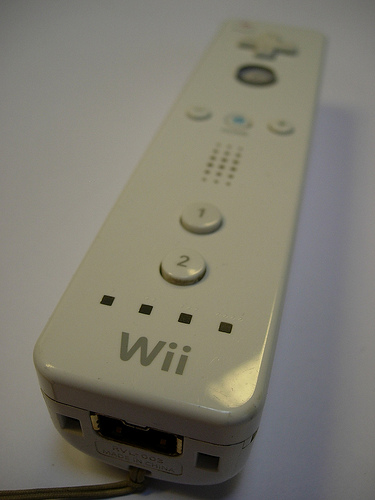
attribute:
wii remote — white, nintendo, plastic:
[16, 14, 341, 483]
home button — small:
[237, 63, 272, 92]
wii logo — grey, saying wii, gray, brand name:
[111, 328, 196, 377]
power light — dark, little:
[137, 302, 156, 317]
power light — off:
[178, 311, 195, 326]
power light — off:
[216, 318, 236, 336]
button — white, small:
[160, 249, 204, 280]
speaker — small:
[200, 137, 250, 189]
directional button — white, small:
[236, 28, 303, 64]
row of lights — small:
[97, 289, 239, 342]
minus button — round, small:
[188, 103, 216, 123]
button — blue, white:
[227, 110, 253, 131]